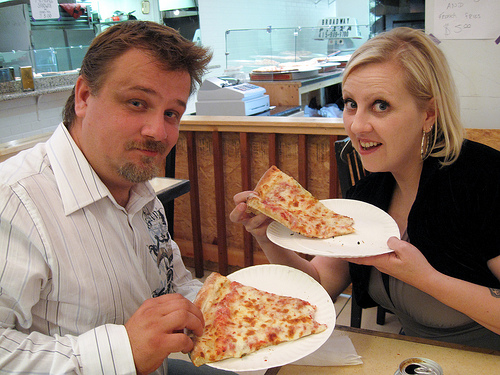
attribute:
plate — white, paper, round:
[265, 196, 399, 261]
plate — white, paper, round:
[183, 260, 336, 374]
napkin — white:
[296, 332, 363, 368]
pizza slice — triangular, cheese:
[246, 163, 352, 241]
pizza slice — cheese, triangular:
[185, 269, 327, 370]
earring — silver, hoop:
[419, 128, 431, 156]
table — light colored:
[265, 324, 498, 374]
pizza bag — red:
[57, 1, 88, 21]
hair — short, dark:
[59, 14, 212, 126]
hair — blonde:
[340, 26, 466, 167]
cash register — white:
[195, 74, 269, 118]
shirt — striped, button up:
[3, 121, 206, 373]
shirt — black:
[332, 137, 499, 346]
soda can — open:
[395, 354, 441, 375]